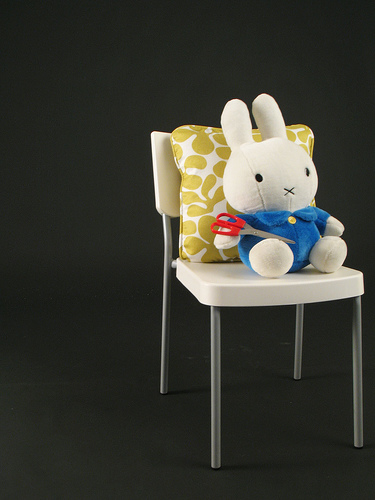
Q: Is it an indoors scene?
A: Yes, it is indoors.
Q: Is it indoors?
A: Yes, it is indoors.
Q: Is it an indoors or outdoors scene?
A: It is indoors.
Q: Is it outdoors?
A: No, it is indoors.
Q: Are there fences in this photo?
A: No, there are no fences.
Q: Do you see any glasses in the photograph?
A: No, there are no glasses.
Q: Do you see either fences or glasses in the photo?
A: No, there are no glasses or fences.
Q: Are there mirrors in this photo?
A: No, there are no mirrors.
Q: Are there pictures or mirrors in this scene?
A: No, there are no mirrors or pictures.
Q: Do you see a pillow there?
A: Yes, there is a pillow.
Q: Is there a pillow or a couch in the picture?
A: Yes, there is a pillow.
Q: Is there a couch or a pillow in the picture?
A: Yes, there is a pillow.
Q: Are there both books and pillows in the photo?
A: No, there is a pillow but no books.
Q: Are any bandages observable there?
A: No, there are no bandages.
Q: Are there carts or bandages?
A: No, there are no bandages or carts.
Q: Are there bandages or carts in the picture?
A: No, there are no bandages or carts.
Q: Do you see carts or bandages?
A: No, there are no bandages or carts.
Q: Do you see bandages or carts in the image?
A: No, there are no bandages or carts.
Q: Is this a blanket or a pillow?
A: This is a pillow.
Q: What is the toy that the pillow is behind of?
A: The toy is a teddy bear.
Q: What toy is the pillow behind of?
A: The pillow is behind the teddy bear.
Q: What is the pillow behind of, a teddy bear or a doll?
A: The pillow is behind a teddy bear.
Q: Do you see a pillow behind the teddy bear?
A: Yes, there is a pillow behind the teddy bear.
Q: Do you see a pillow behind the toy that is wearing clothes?
A: Yes, there is a pillow behind the teddy bear.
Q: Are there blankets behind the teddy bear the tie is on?
A: No, there is a pillow behind the teddy bear.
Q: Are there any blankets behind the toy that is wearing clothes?
A: No, there is a pillow behind the teddy bear.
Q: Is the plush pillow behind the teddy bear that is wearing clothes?
A: Yes, the pillow is behind the teddy bear.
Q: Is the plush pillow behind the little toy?
A: Yes, the pillow is behind the teddy bear.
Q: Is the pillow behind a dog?
A: No, the pillow is behind the teddy bear.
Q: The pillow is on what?
A: The pillow is on the chair.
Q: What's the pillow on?
A: The pillow is on the chair.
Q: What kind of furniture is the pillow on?
A: The pillow is on the chair.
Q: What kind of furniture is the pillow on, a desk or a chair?
A: The pillow is on a chair.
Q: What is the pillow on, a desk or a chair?
A: The pillow is on a chair.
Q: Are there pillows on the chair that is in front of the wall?
A: Yes, there is a pillow on the chair.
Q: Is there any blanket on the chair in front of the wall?
A: No, there is a pillow on the chair.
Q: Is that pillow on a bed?
A: No, the pillow is on the chair.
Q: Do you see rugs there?
A: No, there are no rugs.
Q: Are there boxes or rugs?
A: No, there are no rugs or boxes.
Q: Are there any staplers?
A: No, there are no staplers.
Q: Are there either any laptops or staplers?
A: No, there are no staplers or laptops.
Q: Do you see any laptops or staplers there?
A: No, there are no staplers or laptops.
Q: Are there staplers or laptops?
A: No, there are no staplers or laptops.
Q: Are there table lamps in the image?
A: No, there are no table lamps.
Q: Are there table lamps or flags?
A: No, there are no table lamps or flags.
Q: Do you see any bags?
A: No, there are no bags.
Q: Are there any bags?
A: No, there are no bags.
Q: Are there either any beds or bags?
A: No, there are no bags or beds.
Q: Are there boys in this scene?
A: No, there are no boys.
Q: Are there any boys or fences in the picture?
A: No, there are no boys or fences.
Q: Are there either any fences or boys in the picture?
A: No, there are no boys or fences.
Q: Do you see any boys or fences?
A: No, there are no boys or fences.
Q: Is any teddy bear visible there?
A: Yes, there is a teddy bear.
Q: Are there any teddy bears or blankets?
A: Yes, there is a teddy bear.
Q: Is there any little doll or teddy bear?
A: Yes, there is a little teddy bear.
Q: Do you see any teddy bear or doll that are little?
A: Yes, the teddy bear is little.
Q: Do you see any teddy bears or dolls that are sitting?
A: Yes, the teddy bear is sitting.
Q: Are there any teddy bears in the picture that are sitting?
A: Yes, there is a teddy bear that is sitting.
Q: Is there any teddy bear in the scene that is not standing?
A: Yes, there is a teddy bear that is sitting.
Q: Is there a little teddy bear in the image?
A: Yes, there is a little teddy bear.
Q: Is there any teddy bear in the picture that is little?
A: Yes, there is a teddy bear that is little.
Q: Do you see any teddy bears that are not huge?
A: Yes, there is a little teddy bear.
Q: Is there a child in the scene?
A: No, there are no children.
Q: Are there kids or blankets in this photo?
A: No, there are no kids or blankets.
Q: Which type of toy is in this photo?
A: The toy is a teddy bear.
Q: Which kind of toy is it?
A: The toy is a teddy bear.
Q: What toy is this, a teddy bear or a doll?
A: That is a teddy bear.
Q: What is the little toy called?
A: The toy is a teddy bear.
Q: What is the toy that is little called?
A: The toy is a teddy bear.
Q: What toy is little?
A: The toy is a teddy bear.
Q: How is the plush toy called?
A: The toy is a teddy bear.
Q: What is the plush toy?
A: The toy is a teddy bear.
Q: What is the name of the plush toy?
A: The toy is a teddy bear.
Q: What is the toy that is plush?
A: The toy is a teddy bear.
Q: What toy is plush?
A: The toy is a teddy bear.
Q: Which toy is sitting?
A: The toy is a teddy bear.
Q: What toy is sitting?
A: The toy is a teddy bear.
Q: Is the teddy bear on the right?
A: Yes, the teddy bear is on the right of the image.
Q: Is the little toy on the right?
A: Yes, the teddy bear is on the right of the image.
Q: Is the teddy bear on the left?
A: No, the teddy bear is on the right of the image.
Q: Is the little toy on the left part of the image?
A: No, the teddy bear is on the right of the image.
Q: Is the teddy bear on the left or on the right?
A: The teddy bear is on the right of the image.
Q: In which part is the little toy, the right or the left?
A: The teddy bear is on the right of the image.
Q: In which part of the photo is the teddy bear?
A: The teddy bear is on the right of the image.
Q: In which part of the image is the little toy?
A: The teddy bear is on the right of the image.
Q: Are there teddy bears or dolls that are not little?
A: No, there is a teddy bear but it is little.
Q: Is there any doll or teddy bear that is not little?
A: No, there is a teddy bear but it is little.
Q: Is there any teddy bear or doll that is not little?
A: No, there is a teddy bear but it is little.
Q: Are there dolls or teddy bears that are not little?
A: No, there is a teddy bear but it is little.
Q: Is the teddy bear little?
A: Yes, the teddy bear is little.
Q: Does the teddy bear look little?
A: Yes, the teddy bear is little.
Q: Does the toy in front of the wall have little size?
A: Yes, the teddy bear is little.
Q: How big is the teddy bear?
A: The teddy bear is little.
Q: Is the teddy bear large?
A: No, the teddy bear is little.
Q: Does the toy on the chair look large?
A: No, the teddy bear is little.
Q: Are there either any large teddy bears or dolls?
A: No, there is a teddy bear but it is little.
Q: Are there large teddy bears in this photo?
A: No, there is a teddy bear but it is little.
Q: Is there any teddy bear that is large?
A: No, there is a teddy bear but it is little.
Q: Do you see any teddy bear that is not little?
A: No, there is a teddy bear but it is little.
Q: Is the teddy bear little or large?
A: The teddy bear is little.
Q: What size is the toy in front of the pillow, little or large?
A: The teddy bear is little.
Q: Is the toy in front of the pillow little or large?
A: The teddy bear is little.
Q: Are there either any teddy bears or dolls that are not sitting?
A: No, there is a teddy bear but it is sitting.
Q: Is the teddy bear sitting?
A: Yes, the teddy bear is sitting.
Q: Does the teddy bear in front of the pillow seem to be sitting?
A: Yes, the teddy bear is sitting.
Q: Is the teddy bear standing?
A: No, the teddy bear is sitting.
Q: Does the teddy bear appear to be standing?
A: No, the teddy bear is sitting.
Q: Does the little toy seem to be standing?
A: No, the teddy bear is sitting.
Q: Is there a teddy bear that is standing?
A: No, there is a teddy bear but it is sitting.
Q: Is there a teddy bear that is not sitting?
A: No, there is a teddy bear but it is sitting.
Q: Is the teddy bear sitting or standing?
A: The teddy bear is sitting.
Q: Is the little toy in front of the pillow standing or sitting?
A: The teddy bear is sitting.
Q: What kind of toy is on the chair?
A: The toy is a teddy bear.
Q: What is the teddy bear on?
A: The teddy bear is on the chair.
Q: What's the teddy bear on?
A: The teddy bear is on the chair.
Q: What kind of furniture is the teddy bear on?
A: The teddy bear is on the chair.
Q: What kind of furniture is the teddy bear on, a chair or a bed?
A: The teddy bear is on a chair.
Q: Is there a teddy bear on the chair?
A: Yes, there is a teddy bear on the chair.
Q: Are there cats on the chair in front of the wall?
A: No, there is a teddy bear on the chair.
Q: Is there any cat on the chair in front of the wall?
A: No, there is a teddy bear on the chair.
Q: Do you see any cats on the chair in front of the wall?
A: No, there is a teddy bear on the chair.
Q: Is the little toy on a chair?
A: Yes, the teddy bear is on a chair.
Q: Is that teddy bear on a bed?
A: No, the teddy bear is on a chair.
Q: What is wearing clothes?
A: The teddy bear is wearing clothes.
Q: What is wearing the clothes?
A: The teddy bear is wearing clothes.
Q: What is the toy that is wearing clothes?
A: The toy is a teddy bear.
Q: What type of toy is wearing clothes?
A: The toy is a teddy bear.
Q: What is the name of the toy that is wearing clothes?
A: The toy is a teddy bear.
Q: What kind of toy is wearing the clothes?
A: The toy is a teddy bear.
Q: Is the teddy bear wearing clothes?
A: Yes, the teddy bear is wearing clothes.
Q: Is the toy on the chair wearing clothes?
A: Yes, the teddy bear is wearing clothes.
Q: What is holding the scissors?
A: The teddy bear is holding the scissors.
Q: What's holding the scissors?
A: The teddy bear is holding the scissors.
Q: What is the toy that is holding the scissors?
A: The toy is a teddy bear.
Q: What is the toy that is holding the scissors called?
A: The toy is a teddy bear.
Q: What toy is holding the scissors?
A: The toy is a teddy bear.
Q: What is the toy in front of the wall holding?
A: The teddy bear is holding the scissors.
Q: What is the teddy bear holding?
A: The teddy bear is holding the scissors.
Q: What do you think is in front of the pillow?
A: The teddy bear is in front of the pillow.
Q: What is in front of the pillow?
A: The teddy bear is in front of the pillow.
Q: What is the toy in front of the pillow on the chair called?
A: The toy is a teddy bear.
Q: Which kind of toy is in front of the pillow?
A: The toy is a teddy bear.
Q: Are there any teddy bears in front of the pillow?
A: Yes, there is a teddy bear in front of the pillow.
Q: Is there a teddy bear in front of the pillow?
A: Yes, there is a teddy bear in front of the pillow.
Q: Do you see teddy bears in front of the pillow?
A: Yes, there is a teddy bear in front of the pillow.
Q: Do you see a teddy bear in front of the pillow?
A: Yes, there is a teddy bear in front of the pillow.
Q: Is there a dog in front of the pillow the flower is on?
A: No, there is a teddy bear in front of the pillow.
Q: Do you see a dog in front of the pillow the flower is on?
A: No, there is a teddy bear in front of the pillow.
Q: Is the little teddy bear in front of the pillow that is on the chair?
A: Yes, the teddy bear is in front of the pillow.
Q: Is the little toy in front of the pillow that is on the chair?
A: Yes, the teddy bear is in front of the pillow.